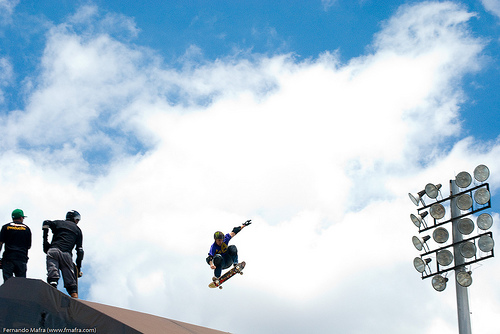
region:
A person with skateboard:
[198, 229, 259, 291]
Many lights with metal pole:
[399, 168, 494, 297]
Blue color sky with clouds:
[101, 30, 403, 113]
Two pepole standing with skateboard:
[7, 202, 107, 294]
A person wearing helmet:
[63, 208, 87, 220]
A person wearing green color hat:
[13, 207, 27, 217]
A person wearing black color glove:
[242, 215, 257, 227]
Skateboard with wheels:
[202, 268, 262, 289]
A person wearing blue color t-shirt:
[203, 243, 230, 253]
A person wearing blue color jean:
[217, 255, 238, 265]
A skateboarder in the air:
[194, 215, 253, 292]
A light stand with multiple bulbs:
[404, 163, 498, 331]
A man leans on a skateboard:
[36, 208, 91, 298]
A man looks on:
[0, 208, 36, 280]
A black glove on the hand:
[243, 215, 255, 228]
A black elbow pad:
[231, 223, 242, 235]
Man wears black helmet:
[216, 230, 223, 244]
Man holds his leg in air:
[207, 229, 229, 286]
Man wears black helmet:
[63, 208, 81, 225]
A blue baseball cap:
[6, 203, 28, 223]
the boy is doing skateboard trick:
[179, 212, 274, 309]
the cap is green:
[7, 204, 32, 226]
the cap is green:
[4, 203, 49, 231]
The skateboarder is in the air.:
[201, 216, 255, 291]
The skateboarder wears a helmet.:
[213, 230, 225, 245]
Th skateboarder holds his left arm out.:
[206, 218, 253, 290]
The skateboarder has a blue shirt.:
[206, 231, 233, 257]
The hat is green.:
[11, 207, 27, 219]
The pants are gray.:
[45, 245, 80, 290]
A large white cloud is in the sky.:
[1, 0, 498, 332]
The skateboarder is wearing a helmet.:
[65, 208, 82, 224]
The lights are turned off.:
[407, 163, 494, 291]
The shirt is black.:
[1, 220, 33, 259]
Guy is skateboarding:
[198, 215, 258, 292]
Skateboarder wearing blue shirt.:
[201, 213, 254, 293]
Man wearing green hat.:
[1, 205, 36, 282]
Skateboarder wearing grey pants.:
[38, 200, 94, 300]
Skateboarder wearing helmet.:
[39, 205, 90, 298]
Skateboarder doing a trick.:
[200, 215, 260, 290]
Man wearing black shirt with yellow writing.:
[0, 207, 35, 284]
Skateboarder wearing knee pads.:
[196, 218, 260, 291]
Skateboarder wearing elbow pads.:
[204, 215, 254, 296]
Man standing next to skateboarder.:
[0, 204, 35, 282]